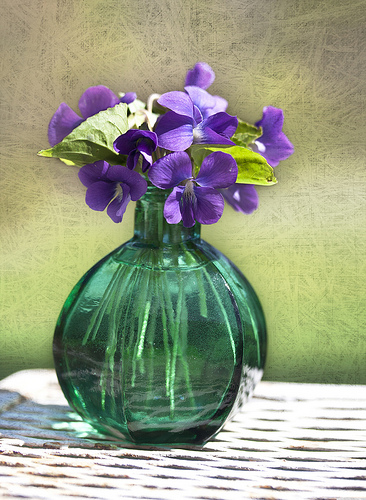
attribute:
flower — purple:
[37, 59, 294, 223]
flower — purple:
[82, 103, 252, 211]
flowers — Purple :
[42, 56, 297, 230]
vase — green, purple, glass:
[42, 182, 275, 453]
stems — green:
[71, 236, 230, 382]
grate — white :
[177, 433, 284, 492]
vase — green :
[75, 179, 314, 336]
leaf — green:
[37, 103, 128, 166]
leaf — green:
[192, 140, 276, 186]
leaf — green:
[226, 114, 262, 143]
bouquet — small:
[35, 62, 305, 237]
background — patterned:
[14, 5, 363, 100]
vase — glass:
[54, 183, 267, 447]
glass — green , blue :
[53, 184, 266, 446]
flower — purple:
[145, 150, 238, 226]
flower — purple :
[103, 69, 298, 210]